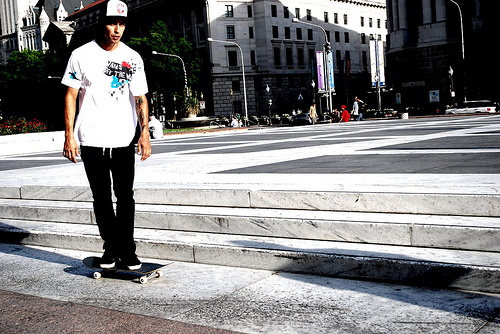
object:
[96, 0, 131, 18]
baseball cap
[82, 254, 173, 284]
skateboard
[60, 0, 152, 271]
man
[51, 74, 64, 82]
lamp post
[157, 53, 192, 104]
lamp post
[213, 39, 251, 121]
lamp post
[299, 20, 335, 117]
lamp post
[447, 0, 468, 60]
lamp post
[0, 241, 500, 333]
sidewalk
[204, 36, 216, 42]
light